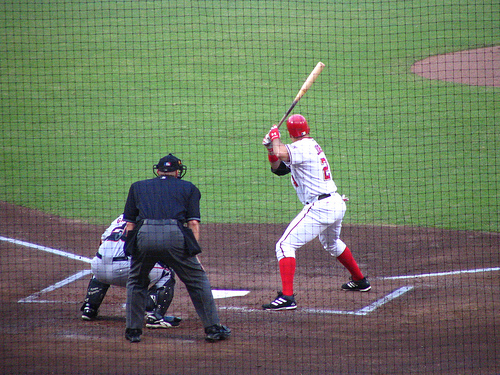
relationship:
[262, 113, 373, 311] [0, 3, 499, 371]
player on top of field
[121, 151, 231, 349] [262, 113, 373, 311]
umpire standing behind player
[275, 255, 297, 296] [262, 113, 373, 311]
sock worn on player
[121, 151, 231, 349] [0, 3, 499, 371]
umpire standing on field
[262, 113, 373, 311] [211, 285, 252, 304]
player standing at home plate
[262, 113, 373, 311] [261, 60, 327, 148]
player holding bat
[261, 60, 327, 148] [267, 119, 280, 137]
bat held in hand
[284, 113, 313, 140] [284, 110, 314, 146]
helmet on top of head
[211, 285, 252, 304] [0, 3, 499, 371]
home plate on top of field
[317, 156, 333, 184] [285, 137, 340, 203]
number on back of shirt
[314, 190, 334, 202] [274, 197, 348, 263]
belt on top of pants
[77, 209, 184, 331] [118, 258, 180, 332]
man has leg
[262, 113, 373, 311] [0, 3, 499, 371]
player playing in field